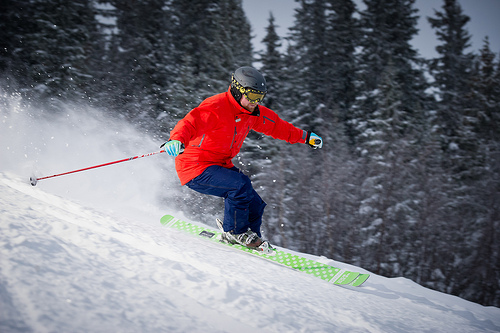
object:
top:
[137, 136, 161, 157]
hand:
[161, 140, 185, 156]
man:
[161, 65, 322, 251]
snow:
[16, 207, 475, 326]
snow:
[33, 202, 158, 303]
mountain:
[2, 156, 457, 328]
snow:
[334, 165, 396, 243]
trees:
[454, 15, 478, 270]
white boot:
[221, 216, 274, 251]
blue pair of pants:
[185, 161, 264, 235]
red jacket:
[161, 85, 308, 189]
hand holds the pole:
[33, 139, 184, 185]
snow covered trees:
[4, 3, 497, 309]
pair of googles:
[306, 131, 324, 150]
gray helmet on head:
[230, 63, 266, 102]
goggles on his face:
[228, 76, 268, 104]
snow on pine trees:
[326, 12, 497, 266]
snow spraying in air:
[2, 75, 183, 229]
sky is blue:
[468, 3, 500, 27]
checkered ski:
[159, 215, 358, 285]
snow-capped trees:
[5, 0, 497, 293]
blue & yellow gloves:
[162, 138, 179, 155]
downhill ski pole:
[28, 140, 182, 186]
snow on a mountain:
[2, 84, 496, 330]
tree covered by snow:
[352, 62, 421, 267]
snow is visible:
[7, 203, 162, 326]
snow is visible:
[144, 230, 201, 332]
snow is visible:
[266, 261, 296, 330]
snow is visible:
[345, 288, 391, 332]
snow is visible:
[368, 287, 429, 329]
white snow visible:
[383, 275, 430, 329]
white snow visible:
[358, 292, 388, 325]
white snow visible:
[2, 288, 497, 331]